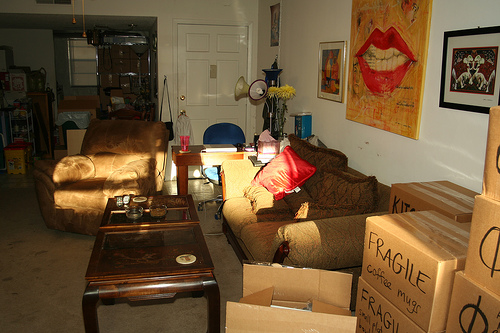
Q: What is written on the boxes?
A: FRAGILE.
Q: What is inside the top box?
A: Coffee mugs.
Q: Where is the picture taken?
A: Inside a home.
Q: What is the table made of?
A: Wood.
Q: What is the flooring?
A: Carpet.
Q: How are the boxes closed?
A: With tape.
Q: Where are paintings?
A: On the wall.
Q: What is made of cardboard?
A: Boxes.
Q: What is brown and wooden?
A: Coffee table.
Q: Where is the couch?
A: Against the wall.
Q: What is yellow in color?
A: Flowers.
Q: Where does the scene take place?
A: In a house.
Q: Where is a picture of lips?
A: On a painting.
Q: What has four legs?
A: The coffee table.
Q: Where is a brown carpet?
A: On the floor.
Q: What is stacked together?
A: Boxes.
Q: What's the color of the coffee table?
A: Brown.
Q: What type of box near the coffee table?
A: Cardboard box.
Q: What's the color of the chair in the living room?
A: Brown.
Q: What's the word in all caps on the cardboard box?
A: FRAGILE.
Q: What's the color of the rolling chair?
A: Blue.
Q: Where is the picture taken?
A: Living room.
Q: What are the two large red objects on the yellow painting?
A: Lips.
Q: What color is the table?
A: Brown.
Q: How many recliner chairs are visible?
A: One.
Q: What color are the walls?
A: White.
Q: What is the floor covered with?
A: Carpet.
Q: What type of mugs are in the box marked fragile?
A: Coffee.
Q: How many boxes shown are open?
A: One.